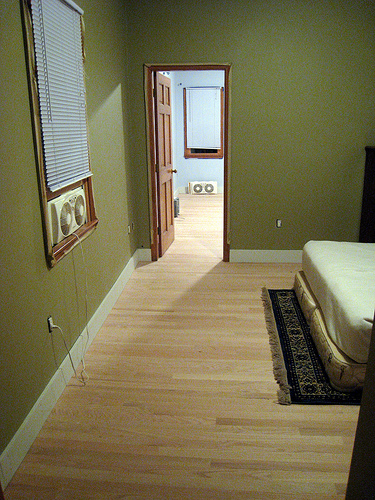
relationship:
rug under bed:
[259, 287, 338, 407] [293, 234, 373, 392]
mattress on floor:
[302, 237, 372, 361] [17, 196, 366, 498]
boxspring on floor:
[290, 270, 368, 392] [17, 196, 366, 498]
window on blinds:
[19, 2, 96, 222] [31, 0, 93, 193]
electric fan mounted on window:
[71, 191, 90, 228] [33, 1, 96, 191]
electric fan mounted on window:
[44, 199, 77, 234] [33, 1, 96, 191]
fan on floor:
[180, 177, 221, 198] [57, 262, 321, 489]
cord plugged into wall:
[52, 234, 90, 388] [4, 5, 128, 496]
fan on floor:
[180, 177, 218, 198] [77, 158, 295, 396]